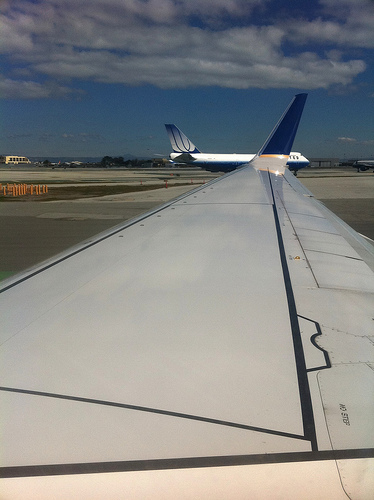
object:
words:
[334, 399, 351, 426]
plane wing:
[3, 93, 374, 493]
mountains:
[47, 153, 166, 169]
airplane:
[152, 92, 324, 176]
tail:
[165, 118, 198, 155]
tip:
[236, 89, 312, 166]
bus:
[5, 155, 32, 166]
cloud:
[32, 44, 364, 89]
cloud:
[55, 38, 132, 84]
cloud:
[2, 0, 62, 27]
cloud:
[311, 2, 369, 36]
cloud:
[1, 71, 77, 100]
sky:
[0, 0, 370, 162]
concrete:
[0, 173, 198, 283]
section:
[1, 3, 71, 75]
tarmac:
[2, 162, 372, 235]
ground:
[0, 182, 143, 211]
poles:
[3, 177, 51, 197]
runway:
[36, 167, 372, 186]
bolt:
[114, 233, 124, 240]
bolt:
[138, 223, 145, 228]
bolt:
[154, 214, 162, 218]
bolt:
[181, 199, 186, 205]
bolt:
[201, 189, 207, 196]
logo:
[165, 124, 201, 155]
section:
[132, 35, 228, 107]